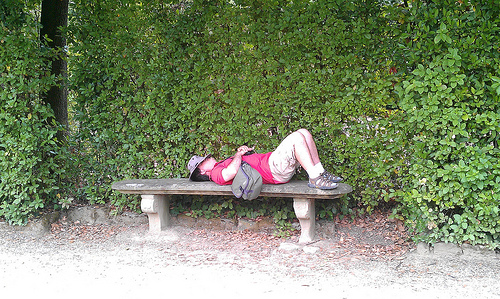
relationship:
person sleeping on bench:
[175, 121, 346, 195] [112, 176, 352, 210]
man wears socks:
[176, 127, 344, 192] [305, 157, 329, 178]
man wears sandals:
[176, 127, 344, 192] [306, 170, 344, 190]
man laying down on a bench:
[187, 126, 353, 198] [108, 169, 352, 244]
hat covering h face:
[183, 150, 201, 176] [201, 152, 218, 170]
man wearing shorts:
[187, 126, 353, 198] [269, 133, 301, 182]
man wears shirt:
[176, 127, 344, 192] [211, 151, 278, 185]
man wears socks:
[147, 109, 377, 206] [296, 155, 336, 181]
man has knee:
[187, 126, 353, 198] [296, 125, 314, 147]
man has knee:
[187, 126, 353, 198] [279, 132, 309, 154]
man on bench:
[179, 126, 339, 196] [110, 179, 335, 227]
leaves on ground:
[179, 217, 288, 252] [2, 191, 497, 297]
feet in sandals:
[307, 171, 361, 201] [311, 176, 341, 190]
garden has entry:
[2, 0, 499, 297] [38, 1, 74, 216]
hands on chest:
[226, 149, 284, 181] [192, 141, 267, 183]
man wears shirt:
[173, 117, 351, 202] [205, 149, 278, 184]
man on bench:
[182, 121, 344, 195] [106, 177, 355, 244]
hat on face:
[182, 152, 208, 173] [195, 154, 218, 171]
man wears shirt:
[173, 109, 379, 211] [210, 152, 275, 185]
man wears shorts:
[176, 127, 344, 192] [269, 140, 295, 182]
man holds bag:
[182, 121, 344, 195] [231, 163, 263, 200]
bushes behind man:
[152, 13, 401, 210] [182, 121, 344, 195]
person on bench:
[187, 124, 342, 198] [106, 177, 355, 244]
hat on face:
[182, 150, 204, 172] [203, 155, 216, 168]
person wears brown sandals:
[186, 127, 343, 189] [305, 172, 345, 189]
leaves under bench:
[207, 229, 267, 264] [181, 212, 280, 247]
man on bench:
[187, 128, 344, 189] [101, 156, 369, 253]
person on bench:
[148, 102, 379, 220] [73, 130, 494, 293]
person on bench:
[181, 131, 343, 192] [102, 170, 362, 252]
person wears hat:
[181, 131, 343, 192] [183, 153, 208, 175]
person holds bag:
[179, 119, 349, 199] [230, 154, 269, 205]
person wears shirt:
[181, 119, 351, 206] [205, 143, 280, 197]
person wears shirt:
[186, 127, 343, 189] [209, 151, 289, 184]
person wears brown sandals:
[172, 130, 344, 207] [308, 171, 343, 189]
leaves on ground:
[42, 201, 409, 266] [5, 207, 497, 262]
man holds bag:
[182, 121, 344, 195] [233, 167, 270, 203]